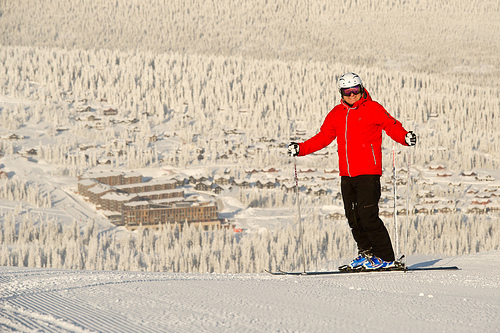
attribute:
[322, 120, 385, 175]
jacket — red, nylon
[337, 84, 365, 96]
snow goggles — black, tinted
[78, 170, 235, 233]
buildings — flat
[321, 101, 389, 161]
jacket — bright red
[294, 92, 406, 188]
jacket — orange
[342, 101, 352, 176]
zippers — silver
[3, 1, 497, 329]
snow — white, grey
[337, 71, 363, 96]
helmet — silver, safety helmet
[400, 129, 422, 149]
glove — black, white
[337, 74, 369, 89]
helmet — silver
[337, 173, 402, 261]
pants — black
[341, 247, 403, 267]
ski boots — blue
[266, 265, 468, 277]
skis — black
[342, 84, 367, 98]
glasses — black, wide eye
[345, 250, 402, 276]
ski boots — blue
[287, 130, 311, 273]
pole — long, supporting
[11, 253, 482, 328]
mountaintop — white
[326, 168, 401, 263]
pants — black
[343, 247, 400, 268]
ski shoes — blue